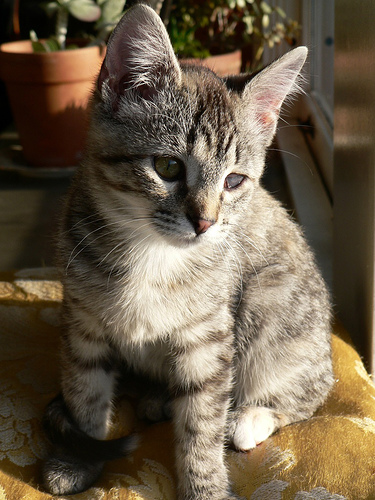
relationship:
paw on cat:
[221, 405, 277, 451] [37, 0, 335, 493]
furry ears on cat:
[127, 20, 162, 82] [37, 0, 335, 493]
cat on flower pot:
[42, 4, 335, 500] [2, 6, 108, 165]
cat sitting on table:
[42, 4, 335, 500] [7, 113, 334, 492]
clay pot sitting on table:
[1, 38, 109, 169] [1, 141, 290, 269]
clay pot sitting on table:
[177, 49, 242, 77] [1, 141, 290, 269]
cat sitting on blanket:
[42, 4, 335, 500] [4, 271, 373, 497]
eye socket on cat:
[225, 170, 244, 190] [37, 0, 335, 493]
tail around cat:
[31, 391, 142, 459] [42, 4, 335, 500]